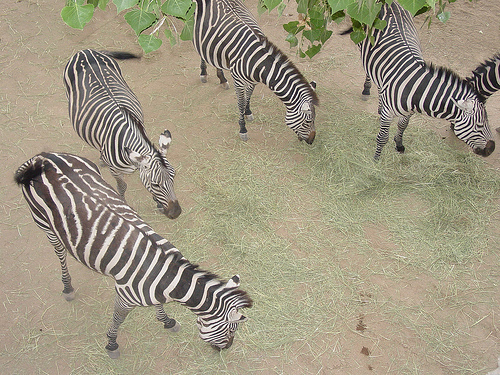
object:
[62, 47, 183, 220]
zebra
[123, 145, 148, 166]
ears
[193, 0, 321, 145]
zebra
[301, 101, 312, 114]
ears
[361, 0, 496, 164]
zebra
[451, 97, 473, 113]
ears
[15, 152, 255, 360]
zebra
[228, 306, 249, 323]
ears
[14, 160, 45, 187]
tail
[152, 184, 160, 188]
eye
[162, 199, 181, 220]
nose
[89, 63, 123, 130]
stripes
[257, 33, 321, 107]
main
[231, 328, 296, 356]
eating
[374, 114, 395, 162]
legs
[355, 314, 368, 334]
spots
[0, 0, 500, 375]
ground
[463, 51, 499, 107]
zebras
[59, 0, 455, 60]
branches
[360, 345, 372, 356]
water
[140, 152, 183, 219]
face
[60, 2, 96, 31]
leaves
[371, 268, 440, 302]
dirt